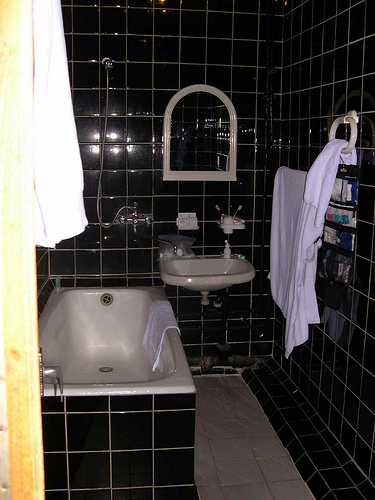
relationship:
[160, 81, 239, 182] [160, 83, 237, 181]
mirror with frame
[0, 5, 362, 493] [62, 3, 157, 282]
bathroom with tiled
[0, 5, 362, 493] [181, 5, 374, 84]
bathroom with tiled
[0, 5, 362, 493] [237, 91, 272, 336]
bathroom with tiled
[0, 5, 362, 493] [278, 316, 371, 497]
bathroom with tiled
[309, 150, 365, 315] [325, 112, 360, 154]
organizer hanging on hanger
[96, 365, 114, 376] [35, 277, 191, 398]
drain on bottom of bath tub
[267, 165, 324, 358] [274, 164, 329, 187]
towel on rack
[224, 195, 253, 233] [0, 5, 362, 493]
tooth brush in bathroom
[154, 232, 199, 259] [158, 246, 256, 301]
bag on sink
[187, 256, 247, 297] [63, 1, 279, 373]
basin mounted on a wall